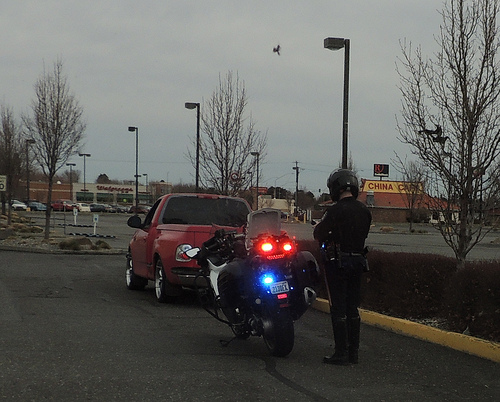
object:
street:
[0, 253, 499, 402]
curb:
[309, 337, 499, 367]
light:
[261, 242, 274, 252]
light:
[264, 277, 273, 284]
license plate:
[270, 280, 290, 295]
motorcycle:
[183, 208, 321, 357]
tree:
[390, 0, 500, 272]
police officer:
[312, 168, 373, 366]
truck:
[124, 192, 254, 302]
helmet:
[325, 167, 359, 202]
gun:
[362, 245, 370, 272]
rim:
[153, 258, 181, 304]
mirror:
[127, 213, 142, 229]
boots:
[323, 314, 361, 366]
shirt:
[313, 196, 373, 255]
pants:
[322, 255, 360, 318]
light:
[283, 244, 292, 251]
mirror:
[184, 246, 201, 258]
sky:
[1, 0, 500, 157]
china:
[368, 182, 394, 191]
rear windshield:
[156, 194, 249, 228]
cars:
[0, 199, 151, 214]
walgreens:
[72, 183, 136, 212]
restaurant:
[320, 178, 461, 235]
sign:
[373, 163, 390, 178]